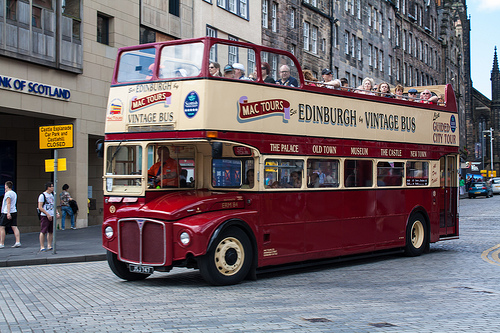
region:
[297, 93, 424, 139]
Words on the side of the bus.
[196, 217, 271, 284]
Wheel on the bus.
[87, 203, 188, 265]
Lights on the front of the bus.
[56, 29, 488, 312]
Bus on the city street.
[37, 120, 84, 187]
Yellow sign on a pole.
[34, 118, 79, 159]
Black letters on a yellow sign.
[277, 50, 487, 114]
People on top of the bus.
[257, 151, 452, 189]
Windows on the bus.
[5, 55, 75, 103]
Sign on the building.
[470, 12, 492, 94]
Sky behind the buildings.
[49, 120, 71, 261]
a yellow sign on a metal pole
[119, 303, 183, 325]
cobblestone in the street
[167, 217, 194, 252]
a shiny headlight on a bus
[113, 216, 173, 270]
the metal grille of a bus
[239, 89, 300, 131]
a logo on the top of the bus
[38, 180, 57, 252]
a man standing on the corner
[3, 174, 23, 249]
a man talking on his phone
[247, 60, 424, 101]
people riding a bus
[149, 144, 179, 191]
a man driving the bus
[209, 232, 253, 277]
a metal wheel on a tire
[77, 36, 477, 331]
Double decker bus on road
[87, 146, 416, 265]
Red color of the bus.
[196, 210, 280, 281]
Wheels on the bus.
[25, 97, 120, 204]
Yellow sign on the pole.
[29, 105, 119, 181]
Black wording on the yellow sign.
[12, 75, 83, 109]
Blue wording on white sign.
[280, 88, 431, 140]
Green lettering on the bus.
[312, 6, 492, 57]
Buildings behind the bus.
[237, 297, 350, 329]
Drain on the street.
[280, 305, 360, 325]
black spot on street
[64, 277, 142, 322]
tiny blue tiles on road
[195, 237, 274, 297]
large shiny black wheel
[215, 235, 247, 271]
white hub cap on black wheel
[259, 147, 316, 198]
large window on red bus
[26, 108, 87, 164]
large yellow street sign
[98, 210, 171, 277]
silver grate on bus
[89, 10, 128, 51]
window in tan building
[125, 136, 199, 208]
bus driver wearing red shirt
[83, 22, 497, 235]
large red passenger bus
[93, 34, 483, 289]
a vintage bus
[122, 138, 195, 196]
a bus driver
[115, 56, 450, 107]
passengers on a bus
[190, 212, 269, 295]
tires on a bus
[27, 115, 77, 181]
street signs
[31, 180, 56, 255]
a man wearing shorts and a backpack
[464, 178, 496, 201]
a car parked on the street.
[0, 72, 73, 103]
a sign on the side of the building.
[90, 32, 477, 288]
a red and beige bus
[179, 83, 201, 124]
a blue decal on a bus